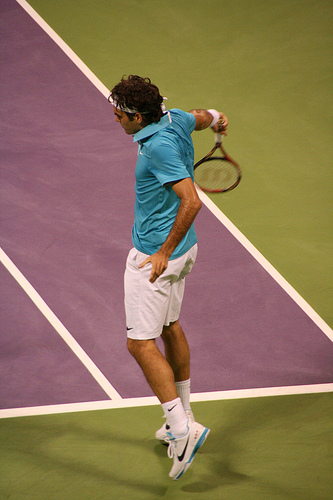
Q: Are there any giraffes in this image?
A: No, there are no giraffes.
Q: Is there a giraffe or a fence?
A: No, there are no giraffes or fences.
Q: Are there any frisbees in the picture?
A: No, there are no frisbees.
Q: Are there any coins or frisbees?
A: No, there are no frisbees or coins.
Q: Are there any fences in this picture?
A: No, there are no fences.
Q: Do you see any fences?
A: No, there are no fences.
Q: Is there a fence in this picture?
A: No, there are no fences.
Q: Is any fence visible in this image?
A: No, there are no fences.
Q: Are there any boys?
A: No, there are no boys.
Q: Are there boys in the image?
A: No, there are no boys.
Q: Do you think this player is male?
A: Yes, the player is male.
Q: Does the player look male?
A: Yes, the player is male.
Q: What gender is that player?
A: The player is male.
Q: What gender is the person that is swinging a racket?
A: The player is male.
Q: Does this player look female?
A: No, the player is male.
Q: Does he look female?
A: No, the player is male.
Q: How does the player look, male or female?
A: The player is male.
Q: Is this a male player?
A: Yes, this is a male player.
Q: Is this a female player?
A: No, this is a male player.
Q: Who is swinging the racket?
A: The player is swinging the racket.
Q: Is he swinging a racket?
A: Yes, the player is swinging a racket.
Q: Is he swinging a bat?
A: No, the player is swinging a racket.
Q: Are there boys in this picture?
A: No, there are no boys.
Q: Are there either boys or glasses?
A: No, there are no boys or glasses.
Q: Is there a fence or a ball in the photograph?
A: No, there are no fences or balls.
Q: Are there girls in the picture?
A: No, there are no girls.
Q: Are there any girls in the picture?
A: No, there are no girls.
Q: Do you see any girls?
A: No, there are no girls.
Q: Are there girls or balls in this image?
A: No, there are no girls or balls.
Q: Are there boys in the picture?
A: No, there are no boys.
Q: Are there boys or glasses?
A: No, there are no boys or glasses.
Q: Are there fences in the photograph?
A: No, there are no fences.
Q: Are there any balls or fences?
A: No, there are no fences or balls.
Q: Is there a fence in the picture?
A: No, there are no fences.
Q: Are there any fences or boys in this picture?
A: No, there are no fences or boys.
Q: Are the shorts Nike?
A: Yes, the shorts are nike.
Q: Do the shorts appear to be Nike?
A: Yes, the shorts are nike.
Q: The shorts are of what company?
A: The shorts are nike.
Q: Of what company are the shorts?
A: The shorts are nike.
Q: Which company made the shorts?
A: Nike made nike.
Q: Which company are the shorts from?
A: The shorts are from nike.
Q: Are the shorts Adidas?
A: No, the shorts are nike.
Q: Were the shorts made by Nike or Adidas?
A: The shorts were made nike.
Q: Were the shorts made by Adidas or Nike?
A: The shorts were made nike.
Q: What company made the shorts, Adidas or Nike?
A: The shorts were made nike.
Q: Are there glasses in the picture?
A: No, there are no glasses.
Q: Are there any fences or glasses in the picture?
A: No, there are no glasses or fences.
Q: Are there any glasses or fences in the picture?
A: No, there are no glasses or fences.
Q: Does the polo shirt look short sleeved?
A: Yes, the polo shirt is short sleeved.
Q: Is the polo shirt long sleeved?
A: No, the polo shirt is short sleeved.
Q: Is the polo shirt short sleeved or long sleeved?
A: The polo shirt is short sleeved.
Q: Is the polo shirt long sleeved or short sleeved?
A: The polo shirt is short sleeved.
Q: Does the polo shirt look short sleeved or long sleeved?
A: The polo shirt is short sleeved.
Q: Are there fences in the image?
A: No, there are no fences.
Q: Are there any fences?
A: No, there are no fences.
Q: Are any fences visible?
A: No, there are no fences.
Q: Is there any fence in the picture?
A: No, there are no fences.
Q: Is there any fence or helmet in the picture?
A: No, there are no fences or helmets.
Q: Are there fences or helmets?
A: No, there are no fences or helmets.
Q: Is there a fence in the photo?
A: No, there are no fences.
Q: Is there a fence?
A: No, there are no fences.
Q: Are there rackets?
A: Yes, there is a racket.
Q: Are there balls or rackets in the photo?
A: Yes, there is a racket.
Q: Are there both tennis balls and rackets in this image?
A: No, there is a racket but no tennis balls.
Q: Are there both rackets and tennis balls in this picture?
A: No, there is a racket but no tennis balls.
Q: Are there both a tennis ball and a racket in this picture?
A: No, there is a racket but no tennis balls.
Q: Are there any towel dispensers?
A: No, there are no towel dispensers.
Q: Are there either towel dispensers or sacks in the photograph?
A: No, there are no towel dispensers or sacks.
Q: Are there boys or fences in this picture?
A: No, there are no fences or boys.